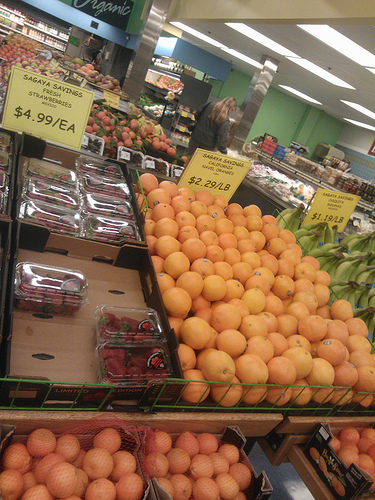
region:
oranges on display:
[110, 143, 351, 404]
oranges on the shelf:
[120, 165, 373, 410]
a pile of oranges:
[138, 153, 374, 401]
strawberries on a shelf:
[7, 117, 221, 435]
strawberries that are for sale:
[4, 103, 188, 413]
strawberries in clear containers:
[15, 101, 180, 401]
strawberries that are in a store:
[20, 120, 177, 452]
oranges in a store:
[114, 111, 370, 427]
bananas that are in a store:
[270, 186, 369, 345]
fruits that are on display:
[23, 120, 371, 460]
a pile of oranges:
[169, 201, 265, 326]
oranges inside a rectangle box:
[140, 421, 279, 499]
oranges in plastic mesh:
[11, 414, 165, 497]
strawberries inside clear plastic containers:
[93, 299, 173, 383]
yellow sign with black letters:
[172, 144, 251, 205]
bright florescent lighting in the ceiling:
[264, 25, 357, 63]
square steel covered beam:
[232, 44, 284, 154]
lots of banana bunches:
[334, 232, 373, 283]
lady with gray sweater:
[184, 85, 262, 159]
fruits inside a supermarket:
[5, 18, 169, 70]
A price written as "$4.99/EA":
[11, 107, 81, 143]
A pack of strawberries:
[95, 304, 165, 341]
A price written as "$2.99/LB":
[186, 176, 234, 198]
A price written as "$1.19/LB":
[309, 209, 347, 226]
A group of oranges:
[199, 236, 275, 327]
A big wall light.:
[297, 22, 374, 74]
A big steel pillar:
[235, 50, 280, 135]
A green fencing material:
[160, 379, 345, 415]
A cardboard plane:
[13, 317, 94, 380]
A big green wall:
[255, 94, 320, 146]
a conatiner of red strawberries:
[87, 303, 172, 342]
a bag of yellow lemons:
[154, 430, 259, 491]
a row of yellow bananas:
[316, 231, 370, 292]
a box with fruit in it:
[313, 431, 355, 494]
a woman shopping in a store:
[200, 92, 250, 138]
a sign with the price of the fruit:
[189, 138, 255, 201]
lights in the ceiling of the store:
[318, 25, 371, 75]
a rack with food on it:
[175, 93, 194, 155]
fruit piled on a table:
[92, 104, 171, 157]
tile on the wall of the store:
[353, 146, 373, 182]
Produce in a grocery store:
[6, 29, 370, 498]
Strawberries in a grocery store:
[94, 304, 167, 382]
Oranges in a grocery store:
[173, 212, 318, 370]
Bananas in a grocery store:
[285, 206, 373, 277]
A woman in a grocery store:
[193, 84, 244, 163]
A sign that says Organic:
[67, 2, 133, 20]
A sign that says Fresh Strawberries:
[28, 84, 74, 108]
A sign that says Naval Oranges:
[200, 162, 237, 175]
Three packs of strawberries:
[14, 246, 173, 384]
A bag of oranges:
[9, 422, 138, 497]